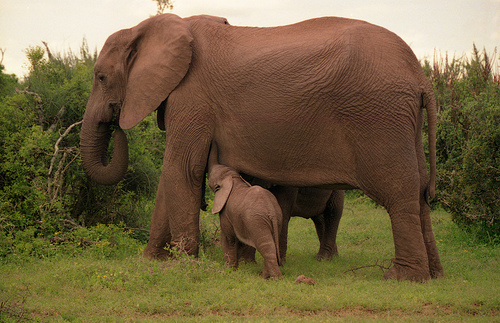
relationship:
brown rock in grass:
[290, 270, 319, 288] [1, 181, 499, 321]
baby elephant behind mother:
[207, 138, 283, 279] [78, 13, 443, 285]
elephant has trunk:
[79, 13, 444, 284] [72, 120, 128, 189]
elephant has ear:
[73, 14, 443, 282] [114, 12, 194, 132]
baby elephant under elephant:
[206, 138, 284, 278] [79, 13, 444, 284]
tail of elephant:
[420, 79, 436, 198] [73, 14, 443, 282]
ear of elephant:
[118, 14, 191, 131] [73, 14, 443, 282]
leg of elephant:
[369, 175, 433, 291] [84, 25, 479, 230]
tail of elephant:
[422, 77, 437, 204] [73, 14, 443, 282]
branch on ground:
[340, 255, 395, 277] [4, 276, 498, 320]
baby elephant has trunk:
[207, 138, 283, 279] [205, 142, 217, 171]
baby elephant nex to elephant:
[207, 138, 283, 279] [73, 14, 443, 282]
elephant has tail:
[73, 14, 443, 282] [420, 90, 440, 210]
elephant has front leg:
[73, 14, 443, 282] [160, 126, 209, 257]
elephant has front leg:
[73, 14, 443, 282] [143, 180, 170, 260]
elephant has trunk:
[73, 14, 443, 282] [75, 89, 133, 185]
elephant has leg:
[73, 14, 443, 282] [369, 75, 451, 281]